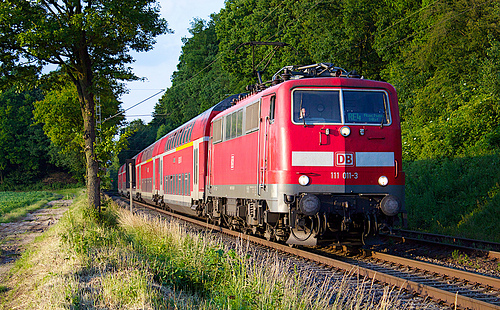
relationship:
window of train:
[242, 99, 258, 132] [118, 58, 401, 258]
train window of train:
[175, 128, 182, 146] [118, 58, 401, 258]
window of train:
[293, 87, 391, 127] [112, 67, 404, 242]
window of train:
[344, 92, 395, 126] [110, 66, 416, 261]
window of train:
[217, 110, 247, 134] [107, 40, 417, 258]